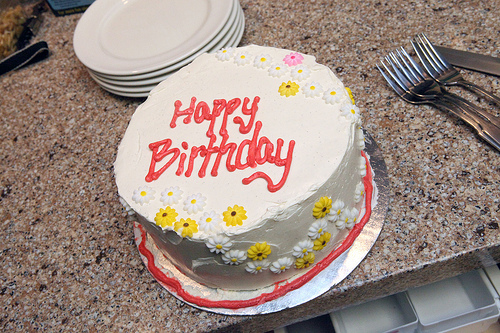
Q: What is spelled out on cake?
A: Happy birthday.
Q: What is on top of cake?
A: White frosting with flower decorations.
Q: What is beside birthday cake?
A: Five plates.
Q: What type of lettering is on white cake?
A: Red lettering.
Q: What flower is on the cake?
A: Daisy.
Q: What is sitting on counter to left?
A: Five white plates.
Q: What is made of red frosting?
A: Letters.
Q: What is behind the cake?
A: Plates.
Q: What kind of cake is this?
A: Birthday.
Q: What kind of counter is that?
A: Graphite.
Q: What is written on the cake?
A: Happy Birthday.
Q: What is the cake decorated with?
A: Flowers.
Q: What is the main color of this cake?
A: White.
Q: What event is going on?
A: Birthday party.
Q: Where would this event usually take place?
A: Dining room.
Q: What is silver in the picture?
A: The forks.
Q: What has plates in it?
A: The picture.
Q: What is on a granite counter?
A: A birthday cake?.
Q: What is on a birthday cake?
A: White and yellow daisies.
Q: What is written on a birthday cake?
A: Happy birthday.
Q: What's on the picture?
A: A stack of plates.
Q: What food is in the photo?
A: Cake.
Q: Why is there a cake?
A: Birthday celebration.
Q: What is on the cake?
A: Frosting.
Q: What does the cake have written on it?
A: Happy Birthday.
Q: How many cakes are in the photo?
A: One.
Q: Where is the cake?
A: On the counter.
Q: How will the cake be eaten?
A: With forks.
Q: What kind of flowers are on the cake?
A: Daisies.